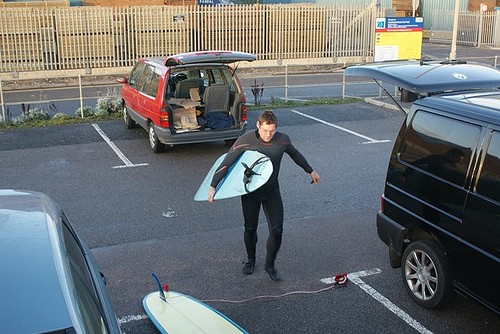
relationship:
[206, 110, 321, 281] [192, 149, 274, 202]
man carrying surfboard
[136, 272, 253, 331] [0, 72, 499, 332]
surfboard laying in parking lot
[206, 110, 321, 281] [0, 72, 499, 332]
man walking in parking lot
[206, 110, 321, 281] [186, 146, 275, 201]
man holding surfboard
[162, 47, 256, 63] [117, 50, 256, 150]
trunk door on red van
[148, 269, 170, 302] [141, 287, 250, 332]
fin on surfboard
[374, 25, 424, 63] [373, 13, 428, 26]
yellow sign with blue banners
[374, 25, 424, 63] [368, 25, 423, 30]
yellow sign with red banners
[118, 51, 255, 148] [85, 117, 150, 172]
van parked on line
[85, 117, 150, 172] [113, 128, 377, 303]
line painted on asphalt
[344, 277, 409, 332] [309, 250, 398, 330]
line painted on asphalt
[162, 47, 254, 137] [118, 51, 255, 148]
hatchback open on van